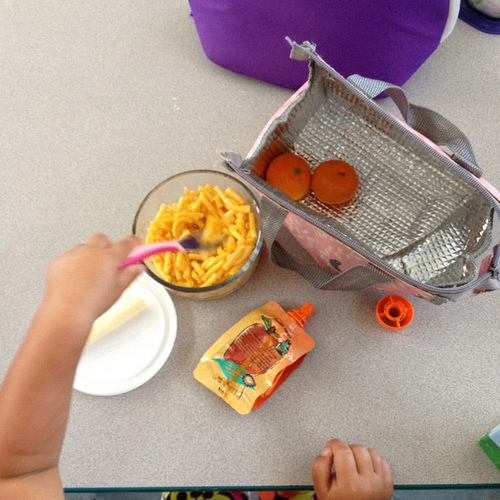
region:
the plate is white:
[22, 270, 206, 412]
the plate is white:
[79, 290, 269, 457]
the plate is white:
[127, 315, 187, 367]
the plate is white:
[90, 345, 227, 413]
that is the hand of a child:
[0, 240, 134, 431]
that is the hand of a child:
[299, 430, 399, 499]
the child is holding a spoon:
[124, 232, 206, 262]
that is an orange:
[262, 147, 310, 199]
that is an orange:
[314, 159, 366, 205]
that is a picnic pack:
[257, 62, 495, 292]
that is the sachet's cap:
[361, 290, 418, 327]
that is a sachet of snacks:
[201, 285, 314, 425]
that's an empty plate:
[79, 277, 174, 388]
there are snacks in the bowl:
[136, 158, 264, 299]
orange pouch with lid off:
[177, 292, 414, 417]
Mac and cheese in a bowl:
[122, 171, 267, 294]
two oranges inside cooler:
[262, 145, 355, 210]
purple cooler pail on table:
[191, 4, 463, 91]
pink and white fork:
[116, 231, 208, 271]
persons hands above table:
[0, 235, 395, 497]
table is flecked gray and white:
[1, 0, 496, 487]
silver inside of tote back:
[258, 73, 493, 283]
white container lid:
[51, 268, 176, 400]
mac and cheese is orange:
[132, 178, 256, 289]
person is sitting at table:
[0, 236, 395, 498]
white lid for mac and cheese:
[51, 266, 178, 396]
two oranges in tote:
[264, 151, 366, 210]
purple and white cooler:
[189, 1, 460, 98]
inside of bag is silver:
[239, 57, 496, 292]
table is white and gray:
[2, 1, 496, 486]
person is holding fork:
[0, 226, 220, 499]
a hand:
[271, 438, 366, 496]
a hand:
[291, 415, 381, 492]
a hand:
[308, 448, 358, 495]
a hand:
[324, 452, 385, 494]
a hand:
[285, 432, 343, 484]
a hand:
[352, 430, 396, 491]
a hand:
[350, 440, 374, 481]